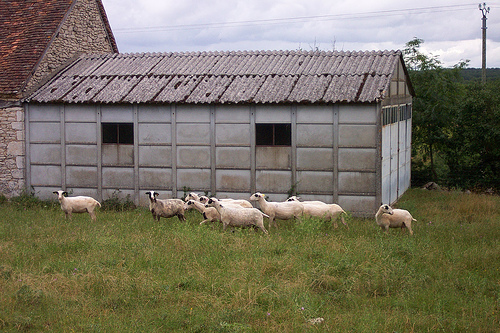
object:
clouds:
[209, 9, 363, 44]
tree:
[407, 50, 464, 191]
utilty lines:
[117, 5, 447, 35]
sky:
[127, 5, 453, 51]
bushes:
[430, 80, 497, 195]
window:
[251, 118, 296, 152]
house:
[0, 0, 381, 193]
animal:
[376, 203, 417, 235]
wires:
[113, 1, 484, 40]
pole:
[476, 1, 491, 68]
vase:
[216, 244, 385, 316]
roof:
[1, 0, 81, 84]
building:
[49, 49, 379, 196]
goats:
[203, 202, 265, 236]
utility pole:
[481, 1, 486, 89]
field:
[1, 223, 497, 330]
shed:
[24, 48, 414, 213]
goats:
[52, 186, 105, 222]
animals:
[52, 189, 99, 218]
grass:
[343, 234, 461, 286]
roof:
[22, 48, 416, 108]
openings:
[92, 118, 138, 148]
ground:
[6, 229, 499, 330]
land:
[8, 225, 500, 328]